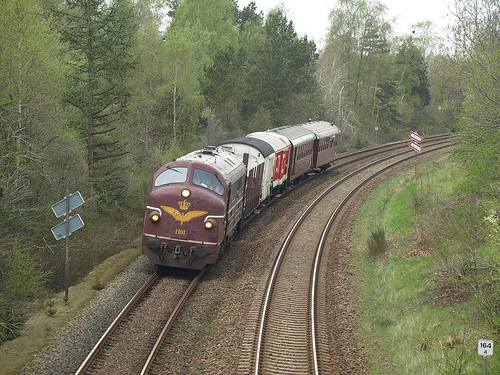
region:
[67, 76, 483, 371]
two sets of train tracks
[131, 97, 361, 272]
train with six cars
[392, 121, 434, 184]
red and white signs on the side of tracks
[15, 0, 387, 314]
train tracks lined with many trees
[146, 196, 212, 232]
yellow design on front of train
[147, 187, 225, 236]
three headlights on front of train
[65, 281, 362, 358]
gravel in between and on the sides of the train tracks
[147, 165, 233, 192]
two windows on front of train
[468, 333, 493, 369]
small white sign with black lettering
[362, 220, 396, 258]
patch of tall green grass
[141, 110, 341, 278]
train on a track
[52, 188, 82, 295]
a sign on a pole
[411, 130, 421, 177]
a red and white sign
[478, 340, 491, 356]
blaxk and white sign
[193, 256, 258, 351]
gravels between tracks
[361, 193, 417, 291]
a bank of grass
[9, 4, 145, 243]
a wooded area of trees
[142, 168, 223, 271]
a brown and yellow front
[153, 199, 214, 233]
a symbol on a train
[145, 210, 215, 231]
lights on a train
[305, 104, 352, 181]
Small brown train cart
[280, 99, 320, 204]
Small brown train cart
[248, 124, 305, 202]
Small brown train cart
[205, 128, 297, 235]
Small brown train cart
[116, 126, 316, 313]
Small brown train cart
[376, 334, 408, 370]
Small green patch of grass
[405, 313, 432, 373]
Small green patch of grass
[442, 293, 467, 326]
Small green patch of grass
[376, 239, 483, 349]
Small green patch of grass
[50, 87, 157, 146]
Small green patch of grass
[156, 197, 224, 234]
TRAIN HAS WINGS ON THE FRONT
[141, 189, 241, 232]
TRAIN HAS THREE HEADLIGHTS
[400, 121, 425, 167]
SIGN IS ON EDGE OF TRACK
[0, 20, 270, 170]
FOLIAGE LINES THE TRACK SIDE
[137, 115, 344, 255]
TRAIN HAS FOUR CARS BEHIND THE ENGINE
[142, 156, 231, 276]
FRONT OF TRAIN IS PURPLE AND YELLOW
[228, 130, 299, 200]
SECOND CAR HAS RED LETTERING ON THE SIDE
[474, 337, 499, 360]
NUMBERS ON SIGN ARE 164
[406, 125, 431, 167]
SIGNS ARE BLACK AND WHITE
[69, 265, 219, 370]
TRAIN IS ON A TRACK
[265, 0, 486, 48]
sunlight in daytime sky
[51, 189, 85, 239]
back of two slanted signs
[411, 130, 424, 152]
front of two slanted signs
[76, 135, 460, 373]
curved rails of tracks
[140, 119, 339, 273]
train with five cars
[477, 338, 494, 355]
black number on white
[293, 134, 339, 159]
windows on side of train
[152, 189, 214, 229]
three glowing lights on train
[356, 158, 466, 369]
green grass on hill